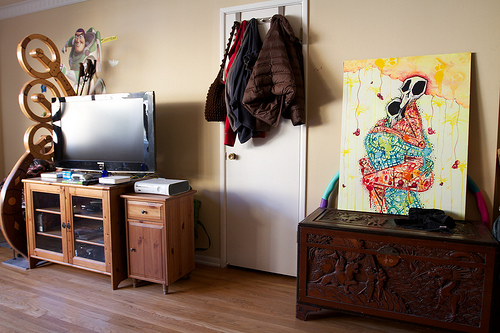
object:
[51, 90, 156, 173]
tv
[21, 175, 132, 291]
table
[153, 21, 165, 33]
wall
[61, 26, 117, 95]
sticker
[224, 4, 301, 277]
door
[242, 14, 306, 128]
coats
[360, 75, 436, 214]
art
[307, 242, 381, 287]
stand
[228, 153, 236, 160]
knob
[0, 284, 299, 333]
floor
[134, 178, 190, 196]
xbox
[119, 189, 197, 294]
cabinet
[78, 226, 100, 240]
games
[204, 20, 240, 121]
purse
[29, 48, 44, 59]
statue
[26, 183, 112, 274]
doors